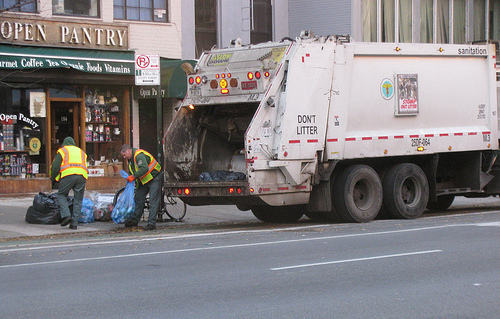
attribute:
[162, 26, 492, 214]
whiite truck — large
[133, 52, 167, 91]
sign — white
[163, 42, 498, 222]
truck — white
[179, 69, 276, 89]
lights — yellow, red